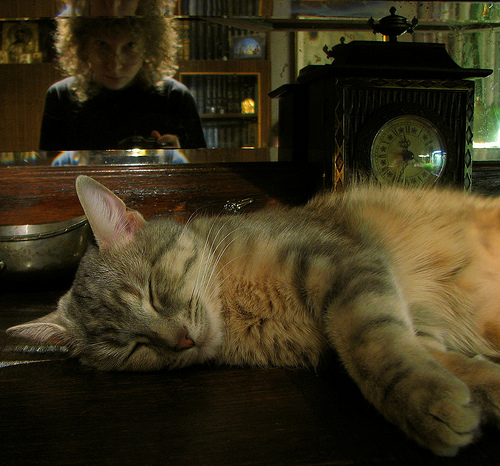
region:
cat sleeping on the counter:
[10, 164, 495, 441]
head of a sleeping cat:
[3, 164, 234, 386]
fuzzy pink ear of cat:
[68, 168, 150, 260]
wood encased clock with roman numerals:
[293, 33, 483, 198]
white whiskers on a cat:
[185, 212, 257, 324]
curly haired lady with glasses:
[36, 6, 213, 148]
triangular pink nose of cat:
[163, 315, 208, 371]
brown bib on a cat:
[230, 283, 306, 358]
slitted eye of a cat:
[136, 264, 176, 316]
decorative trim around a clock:
[324, 70, 355, 185]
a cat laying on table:
[14, 115, 490, 392]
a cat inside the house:
[16, 107, 493, 464]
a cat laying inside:
[44, 120, 498, 410]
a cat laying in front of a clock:
[109, 39, 499, 384]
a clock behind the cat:
[279, 38, 497, 248]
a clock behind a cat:
[307, 43, 497, 305]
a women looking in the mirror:
[46, 35, 300, 227]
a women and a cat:
[8, 3, 496, 430]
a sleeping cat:
[16, 95, 483, 462]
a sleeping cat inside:
[19, 114, 498, 424]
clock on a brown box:
[250, 39, 492, 226]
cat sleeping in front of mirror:
[42, 170, 499, 440]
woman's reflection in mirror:
[46, 21, 226, 160]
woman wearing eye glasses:
[81, 31, 177, 71]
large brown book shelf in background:
[166, 5, 286, 157]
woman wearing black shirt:
[22, 73, 236, 167]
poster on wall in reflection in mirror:
[290, 10, 417, 88]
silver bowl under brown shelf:
[3, 175, 94, 280]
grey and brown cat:
[76, 219, 497, 459]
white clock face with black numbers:
[371, 102, 458, 198]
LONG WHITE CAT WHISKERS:
[163, 205, 275, 368]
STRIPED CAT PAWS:
[280, 236, 484, 445]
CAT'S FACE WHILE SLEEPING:
[31, 208, 266, 411]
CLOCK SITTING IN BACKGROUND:
[284, 17, 497, 187]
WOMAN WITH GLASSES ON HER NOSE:
[65, 37, 172, 76]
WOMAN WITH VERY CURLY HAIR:
[40, 2, 205, 122]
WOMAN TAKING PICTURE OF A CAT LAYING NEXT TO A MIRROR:
[14, 5, 286, 266]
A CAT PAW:
[381, 335, 480, 457]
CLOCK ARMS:
[384, 121, 435, 191]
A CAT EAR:
[31, 148, 174, 278]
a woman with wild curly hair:
[48, 8, 186, 98]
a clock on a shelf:
[309, 18, 482, 227]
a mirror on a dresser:
[5, 7, 333, 171]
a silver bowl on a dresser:
[2, 186, 105, 279]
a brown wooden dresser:
[1, 173, 494, 462]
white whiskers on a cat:
[187, 212, 250, 310]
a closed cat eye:
[145, 269, 167, 316]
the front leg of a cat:
[323, 251, 488, 448]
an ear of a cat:
[71, 171, 148, 256]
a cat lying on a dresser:
[10, 162, 499, 451]